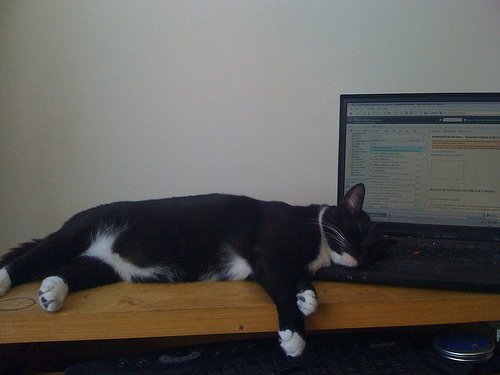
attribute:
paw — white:
[276, 327, 304, 361]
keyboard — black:
[342, 211, 497, 295]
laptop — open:
[335, 61, 497, 279]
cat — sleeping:
[0, 182, 372, 357]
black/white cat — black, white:
[0, 182, 395, 354]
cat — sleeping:
[40, 185, 337, 320]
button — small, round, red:
[407, 245, 421, 260]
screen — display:
[347, 102, 499, 226]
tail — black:
[2, 234, 52, 269]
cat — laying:
[1, 177, 401, 359]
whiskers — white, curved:
[314, 215, 349, 250]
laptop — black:
[311, 92, 498, 295]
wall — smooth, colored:
[2, 1, 496, 203]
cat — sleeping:
[99, 167, 309, 297]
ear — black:
[339, 183, 367, 215]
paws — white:
[270, 287, 335, 363]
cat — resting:
[13, 167, 394, 348]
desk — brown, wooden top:
[104, 265, 274, 347]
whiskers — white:
[316, 217, 351, 252]